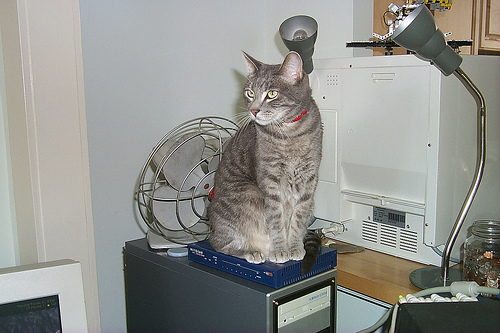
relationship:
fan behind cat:
[133, 116, 240, 246] [206, 44, 321, 272]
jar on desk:
[447, 205, 499, 297] [443, 283, 498, 331]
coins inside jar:
[461, 244, 499, 284] [459, 218, 498, 286]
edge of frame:
[0, 251, 89, 275] [3, 255, 98, 330]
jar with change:
[458, 219, 500, 297] [462, 241, 499, 289]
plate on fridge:
[368, 203, 404, 230] [299, 47, 499, 274]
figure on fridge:
[367, 3, 434, 47] [313, 52, 498, 268]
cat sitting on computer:
[206, 44, 321, 272] [120, 238, 341, 331]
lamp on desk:
[277, 14, 318, 74] [322, 235, 462, 302]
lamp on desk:
[367, 3, 487, 297] [322, 235, 462, 302]